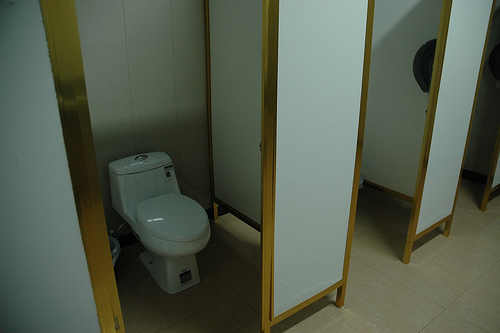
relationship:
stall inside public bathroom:
[74, 1, 264, 331] [0, 0, 499, 332]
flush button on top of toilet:
[135, 153, 149, 162] [109, 149, 212, 294]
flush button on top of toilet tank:
[135, 153, 149, 162] [108, 150, 181, 215]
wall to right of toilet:
[207, 0, 262, 230] [109, 149, 212, 294]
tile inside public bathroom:
[350, 208, 500, 308] [0, 0, 499, 332]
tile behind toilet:
[125, 41, 176, 108] [109, 149, 212, 294]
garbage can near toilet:
[108, 235, 122, 268] [109, 149, 212, 294]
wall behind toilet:
[76, 0, 212, 248] [109, 149, 212, 294]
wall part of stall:
[261, 2, 376, 331] [74, 1, 264, 331]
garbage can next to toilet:
[108, 235, 122, 268] [109, 149, 212, 294]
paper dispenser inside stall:
[412, 38, 437, 93] [332, 1, 496, 308]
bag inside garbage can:
[107, 234, 121, 268] [108, 235, 122, 268]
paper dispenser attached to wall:
[412, 38, 437, 93] [364, 1, 442, 201]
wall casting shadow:
[207, 0, 262, 230] [116, 223, 337, 332]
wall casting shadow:
[364, 1, 442, 201] [358, 186, 446, 259]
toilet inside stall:
[109, 149, 212, 294] [74, 1, 264, 331]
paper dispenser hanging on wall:
[412, 38, 437, 93] [364, 1, 442, 201]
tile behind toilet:
[75, 1, 128, 46] [109, 149, 212, 294]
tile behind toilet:
[123, 1, 171, 46] [109, 149, 212, 294]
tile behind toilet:
[83, 44, 129, 99] [109, 149, 212, 294]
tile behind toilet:
[174, 97, 209, 145] [109, 149, 212, 294]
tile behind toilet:
[173, 44, 207, 94] [109, 149, 212, 294]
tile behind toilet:
[171, 1, 213, 53] [109, 149, 212, 294]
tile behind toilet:
[92, 103, 134, 149] [109, 149, 212, 294]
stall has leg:
[74, 1, 264, 331] [336, 286, 346, 307]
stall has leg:
[74, 1, 264, 331] [264, 325, 272, 331]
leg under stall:
[403, 236, 414, 262] [332, 1, 496, 308]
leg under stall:
[444, 217, 452, 236] [332, 1, 496, 308]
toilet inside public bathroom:
[109, 149, 212, 294] [0, 0, 499, 332]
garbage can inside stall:
[358, 174, 365, 192] [332, 1, 496, 308]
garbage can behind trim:
[108, 235, 122, 268] [41, 1, 126, 331]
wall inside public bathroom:
[261, 2, 376, 331] [0, 0, 499, 332]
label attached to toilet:
[162, 162, 176, 183] [109, 149, 212, 294]